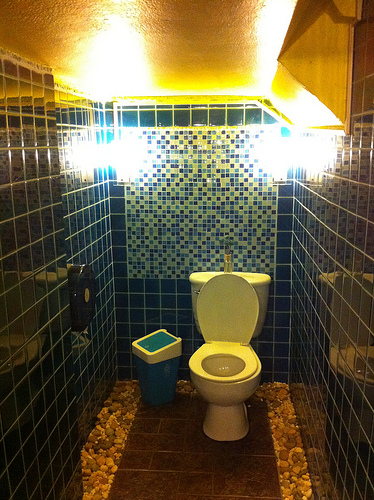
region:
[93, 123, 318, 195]
The lights are on.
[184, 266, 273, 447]
The toilet is white.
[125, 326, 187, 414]
The trash is blue.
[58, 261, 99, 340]
The dispenser is black.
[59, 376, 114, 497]
The rocks are on the ground.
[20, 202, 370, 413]
The tile is blue.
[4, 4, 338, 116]
The ceiling is yellow.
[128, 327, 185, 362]
The lid is white.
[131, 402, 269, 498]
The tile is brown.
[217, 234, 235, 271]
The bottle is on the toilet.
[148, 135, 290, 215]
blue tile in the bathroom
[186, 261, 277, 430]
white toilet in the bathroom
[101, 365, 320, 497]
rocks on the floor in the bathroom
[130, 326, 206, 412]
blue trash can with white band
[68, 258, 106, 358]
round toilet paper dispenser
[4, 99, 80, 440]
shiny blue square tiles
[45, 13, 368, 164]
ceiling has yellow lights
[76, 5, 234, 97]
ceiling has popcorn surface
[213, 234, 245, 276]
can on toilet tank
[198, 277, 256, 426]
toilet seat is open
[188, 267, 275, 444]
white toilet in a small bathroom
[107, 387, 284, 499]
brown tiles on a floor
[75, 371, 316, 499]
rocks on a bathroom floor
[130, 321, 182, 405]
blue and white trashcan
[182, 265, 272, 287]
lid on the toilet tank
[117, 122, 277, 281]
mosaic of tiles behind the toilet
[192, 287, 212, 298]
silver handle on a toilet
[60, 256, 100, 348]
black and grey toilet paper dispenser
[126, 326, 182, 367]
white trash can lid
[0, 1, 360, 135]
ceiling in a bathroom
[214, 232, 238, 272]
A plant in a vase sits behind the toilet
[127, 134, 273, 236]
A portion of the wall has blue and white decorative tiles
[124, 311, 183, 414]
A blue trash can sits by the toilet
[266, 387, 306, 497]
Some of the floor is decorated with rocks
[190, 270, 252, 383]
The toilet lid is open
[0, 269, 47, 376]
A reflection of the toilet is on the wall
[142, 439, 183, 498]
There are brown tiles on the floor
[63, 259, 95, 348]
Toilet paper dispenser is on the wall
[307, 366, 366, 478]
The walls are blue tile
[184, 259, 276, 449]
The toilet is white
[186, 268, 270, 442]
White toilet with lid up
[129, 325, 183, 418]
Blue and white trash can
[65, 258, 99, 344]
Toilet paper dispenser on wall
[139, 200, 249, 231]
Checkered bathroom wall tile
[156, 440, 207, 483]
Brown bathroom floor tile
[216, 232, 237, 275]
Decoration on toilet tank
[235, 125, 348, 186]
Light reflection on bathroom wall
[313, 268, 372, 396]
Reflection of toilet on bathroom wall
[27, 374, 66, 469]
Blue bathroom wall tile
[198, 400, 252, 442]
White base of toilet